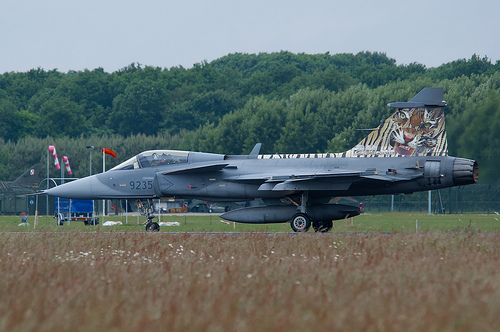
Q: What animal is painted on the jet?
A: Tiger.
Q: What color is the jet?
A: Grey.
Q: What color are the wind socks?
A: Red, white.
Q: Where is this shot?
A: Air field.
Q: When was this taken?
A: Daytime.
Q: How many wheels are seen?
A: 3.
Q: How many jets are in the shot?
A: 1.